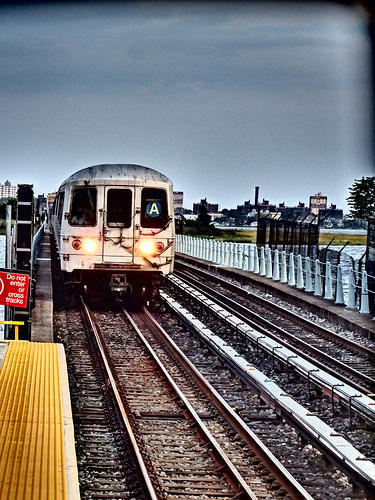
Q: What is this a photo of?
A: A train.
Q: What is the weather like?
A: Cloudy.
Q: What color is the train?
A: White.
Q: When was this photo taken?
A: During the day.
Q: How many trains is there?
A: One.